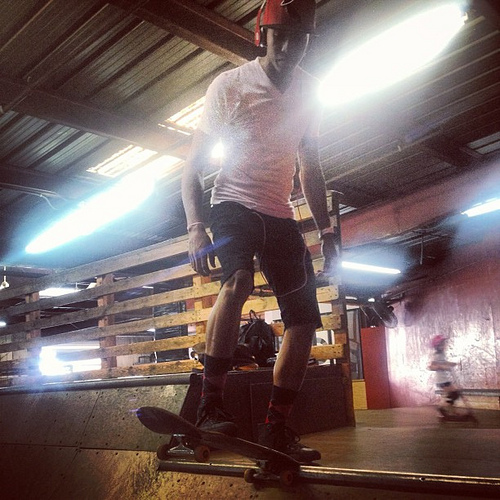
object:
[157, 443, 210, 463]
wheels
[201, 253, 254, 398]
leg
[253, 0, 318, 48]
helmet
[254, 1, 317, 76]
head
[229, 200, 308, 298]
cord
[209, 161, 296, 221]
waist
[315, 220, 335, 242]
wrist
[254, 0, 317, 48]
hat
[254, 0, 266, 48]
headphones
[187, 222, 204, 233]
band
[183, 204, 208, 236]
wrist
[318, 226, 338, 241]
watch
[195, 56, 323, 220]
shirt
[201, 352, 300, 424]
socks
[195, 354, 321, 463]
shoes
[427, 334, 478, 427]
child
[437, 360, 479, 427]
scooter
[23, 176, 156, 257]
light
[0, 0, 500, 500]
building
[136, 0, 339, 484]
man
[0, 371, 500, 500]
ramp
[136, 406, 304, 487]
hint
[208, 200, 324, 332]
short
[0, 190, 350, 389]
fence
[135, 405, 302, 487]
board